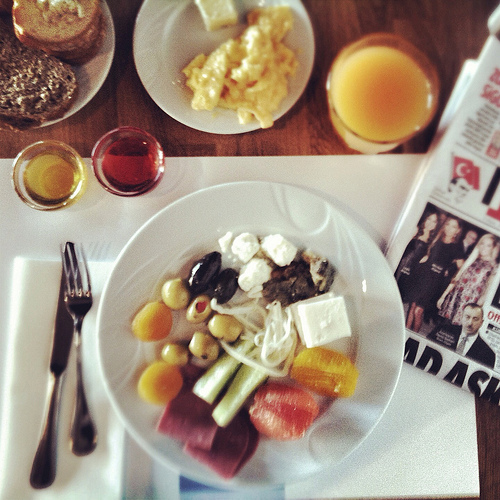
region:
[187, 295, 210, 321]
green olive on round white plate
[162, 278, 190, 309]
green olive on round white plate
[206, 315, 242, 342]
green olive on round white plate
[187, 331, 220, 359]
green olive on round white plate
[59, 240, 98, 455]
silver fork next to white plate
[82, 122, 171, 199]
Red liquid in a cup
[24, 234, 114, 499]
Fork and knife on a napkin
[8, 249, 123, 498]
White napkin with a fork and knife on it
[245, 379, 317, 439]
Pink grapefruit on a plate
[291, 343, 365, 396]
Orange on a plate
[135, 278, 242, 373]
Olives on a plate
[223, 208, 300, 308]
Cheese on a plate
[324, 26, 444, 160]
Orange liquid in a large cup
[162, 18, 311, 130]
Scrambled eggs on a plate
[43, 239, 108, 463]
silver fork on napkin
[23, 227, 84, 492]
silver knife on napkin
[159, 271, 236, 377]
green olives on plate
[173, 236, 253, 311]
black olives on plate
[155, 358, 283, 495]
sandwich meat on plate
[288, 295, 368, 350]
cheese squares on plate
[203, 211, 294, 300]
feta cheese on plate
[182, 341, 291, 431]
pickles on plate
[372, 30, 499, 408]
news paper on table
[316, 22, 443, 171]
glass of orange juice on table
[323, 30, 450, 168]
glass of orange juice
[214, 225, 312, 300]
pieces of feta on plate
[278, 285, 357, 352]
cheese squares on plate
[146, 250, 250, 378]
green olives on plate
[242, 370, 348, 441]
grapefruit on plate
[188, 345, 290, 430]
pickles on plate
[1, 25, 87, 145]
sliced brown bread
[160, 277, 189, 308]
green olive on white round plate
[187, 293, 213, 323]
green olive on white round plate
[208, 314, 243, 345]
green olive on white round plate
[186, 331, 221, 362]
green olive on white round plate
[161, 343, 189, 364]
green olive on white round plate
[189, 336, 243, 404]
celery stick next to celery stick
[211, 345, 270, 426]
celery stick next to celery stick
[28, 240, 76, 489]
silver knife on white napkin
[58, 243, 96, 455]
silver fork on white napkin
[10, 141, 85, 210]
small glass next to small glass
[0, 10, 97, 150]
sliced of bread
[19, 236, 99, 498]
silver knife on napkin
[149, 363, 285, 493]
sandwich meat on plate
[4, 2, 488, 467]
a spread of breakfast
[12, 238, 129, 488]
a pair of silverware on a napkin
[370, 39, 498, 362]
a newspaper next to a plate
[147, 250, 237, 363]
different varieties of olives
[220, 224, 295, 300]
small pieces of white cheese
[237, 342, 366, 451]
cut portions of citrus fruit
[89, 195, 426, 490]
a plate of food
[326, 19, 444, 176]
a glass of orange juice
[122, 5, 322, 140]
a plate of scrambled eggs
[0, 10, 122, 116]
different kinds of toast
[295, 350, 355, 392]
food on a plate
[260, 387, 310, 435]
food on a plate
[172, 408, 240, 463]
food on a plate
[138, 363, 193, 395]
food on a plate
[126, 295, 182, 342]
food on a plate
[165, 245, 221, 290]
food on a plate